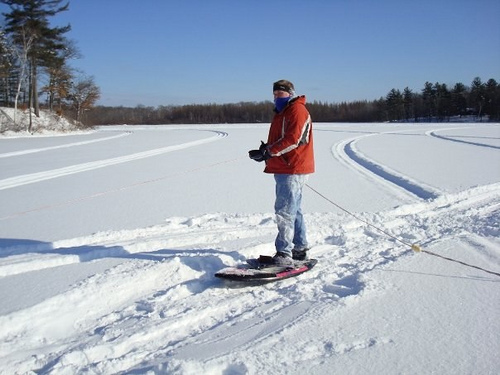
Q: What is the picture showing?
A: It is showing a field.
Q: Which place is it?
A: It is a field.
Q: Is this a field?
A: Yes, it is a field.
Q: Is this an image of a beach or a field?
A: It is showing a field.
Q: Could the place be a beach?
A: No, it is a field.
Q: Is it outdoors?
A: Yes, it is outdoors.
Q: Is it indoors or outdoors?
A: It is outdoors.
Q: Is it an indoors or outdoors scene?
A: It is outdoors.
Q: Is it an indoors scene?
A: No, it is outdoors.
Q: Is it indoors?
A: No, it is outdoors.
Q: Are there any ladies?
A: No, there are no ladies.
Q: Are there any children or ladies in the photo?
A: No, there are no ladies or children.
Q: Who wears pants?
A: The man wears pants.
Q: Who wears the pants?
A: The man wears pants.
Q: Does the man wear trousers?
A: Yes, the man wears trousers.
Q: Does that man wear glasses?
A: No, the man wears trousers.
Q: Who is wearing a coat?
A: The man is wearing a coat.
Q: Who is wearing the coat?
A: The man is wearing a coat.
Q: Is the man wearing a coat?
A: Yes, the man is wearing a coat.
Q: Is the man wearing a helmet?
A: No, the man is wearing a coat.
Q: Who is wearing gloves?
A: The man is wearing gloves.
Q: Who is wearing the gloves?
A: The man is wearing gloves.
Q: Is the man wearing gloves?
A: Yes, the man is wearing gloves.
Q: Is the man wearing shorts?
A: No, the man is wearing gloves.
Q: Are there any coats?
A: Yes, there is a coat.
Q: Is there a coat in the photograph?
A: Yes, there is a coat.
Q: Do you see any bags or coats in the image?
A: Yes, there is a coat.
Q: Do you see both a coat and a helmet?
A: No, there is a coat but no helmets.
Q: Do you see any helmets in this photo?
A: No, there are no helmets.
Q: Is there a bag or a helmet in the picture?
A: No, there are no helmets or bags.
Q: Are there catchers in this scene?
A: No, there are no catchers.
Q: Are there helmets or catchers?
A: No, there are no catchers or helmets.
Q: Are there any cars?
A: No, there are no cars.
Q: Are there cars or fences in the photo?
A: No, there are no cars or fences.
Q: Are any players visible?
A: No, there are no players.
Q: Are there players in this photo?
A: No, there are no players.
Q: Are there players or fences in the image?
A: No, there are no players or fences.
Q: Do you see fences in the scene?
A: No, there are no fences.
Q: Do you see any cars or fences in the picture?
A: No, there are no fences or cars.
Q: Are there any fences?
A: No, there are no fences.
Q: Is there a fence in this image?
A: No, there are no fences.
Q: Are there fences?
A: No, there are no fences.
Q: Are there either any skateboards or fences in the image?
A: No, there are no fences or skateboards.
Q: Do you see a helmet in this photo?
A: No, there are no helmets.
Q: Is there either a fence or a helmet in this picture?
A: No, there are no helmets or fences.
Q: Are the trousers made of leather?
A: No, the trousers are made of denim.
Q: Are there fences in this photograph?
A: No, there are no fences.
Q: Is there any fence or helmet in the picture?
A: No, there are no fences or helmets.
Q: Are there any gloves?
A: Yes, there are gloves.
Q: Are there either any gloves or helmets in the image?
A: Yes, there are gloves.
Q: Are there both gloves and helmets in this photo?
A: No, there are gloves but no helmets.